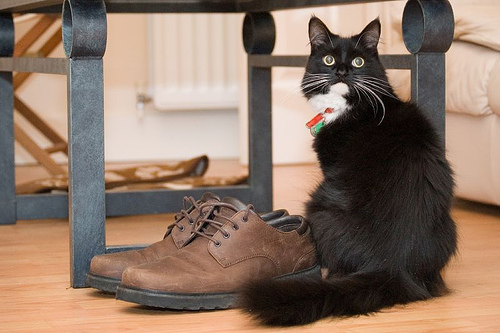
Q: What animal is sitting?
A: A cat.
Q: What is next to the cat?
A: The shoes.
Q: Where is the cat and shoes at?
A: In a room.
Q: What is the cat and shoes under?
A: A table.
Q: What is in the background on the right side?
A: A couch.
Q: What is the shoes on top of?
A: The floor.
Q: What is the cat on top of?
A: The floor.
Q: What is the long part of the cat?
A: The tail.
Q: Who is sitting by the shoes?
A: A cat.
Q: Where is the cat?
A: Sitting next to the shoes.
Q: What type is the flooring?
A: Wooden.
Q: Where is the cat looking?
A: Straight ahead.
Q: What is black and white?
A: The cat.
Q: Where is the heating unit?
A: On the wall.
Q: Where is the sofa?
A: On the right.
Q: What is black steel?
A: The chair legs.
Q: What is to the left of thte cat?
A: A pair of shoes.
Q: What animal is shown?
A: A cat.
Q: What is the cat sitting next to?
A: Shoes.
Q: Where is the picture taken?
A: A living toom.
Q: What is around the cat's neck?
A: A ribbon.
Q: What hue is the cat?
A: Black and white.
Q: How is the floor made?
A: Of wood.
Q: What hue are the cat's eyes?
A: Yellow.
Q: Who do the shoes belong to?
A: A man.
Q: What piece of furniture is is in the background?
A: A couch.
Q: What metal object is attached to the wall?
A: A radiator.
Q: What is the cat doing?
A: Sitting.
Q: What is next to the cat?
A: Shoes.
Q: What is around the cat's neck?
A: Collar.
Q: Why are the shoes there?
A: Someone put them there.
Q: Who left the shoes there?
A: A person.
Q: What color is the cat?
A: Black.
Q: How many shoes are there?
A: Two.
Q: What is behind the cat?
A: Couch.